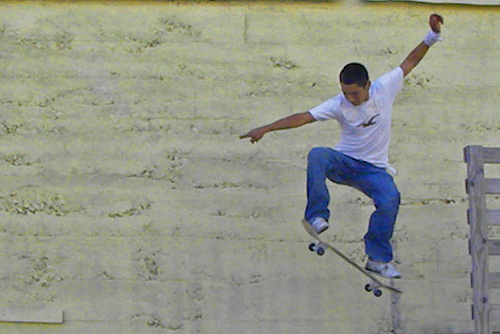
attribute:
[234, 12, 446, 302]
boy — jumping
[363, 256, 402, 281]
skate shoe — a pair of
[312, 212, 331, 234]
skate shoe — a pair of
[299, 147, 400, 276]
jeans — blue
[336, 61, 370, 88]
hair — black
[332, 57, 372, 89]
hair — shaved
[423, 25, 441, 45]
sweatband — white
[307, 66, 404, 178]
t-shirt — white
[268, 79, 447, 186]
shirt — white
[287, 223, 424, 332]
skateboard trick — doing a skateboard trick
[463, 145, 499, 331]
pallet — wooden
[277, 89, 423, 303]
boy — skating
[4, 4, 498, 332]
wall — cracking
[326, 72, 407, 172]
shirt — white, hollister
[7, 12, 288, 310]
wall — grey, brick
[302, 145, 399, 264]
jeans — blue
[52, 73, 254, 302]
wall — concrete